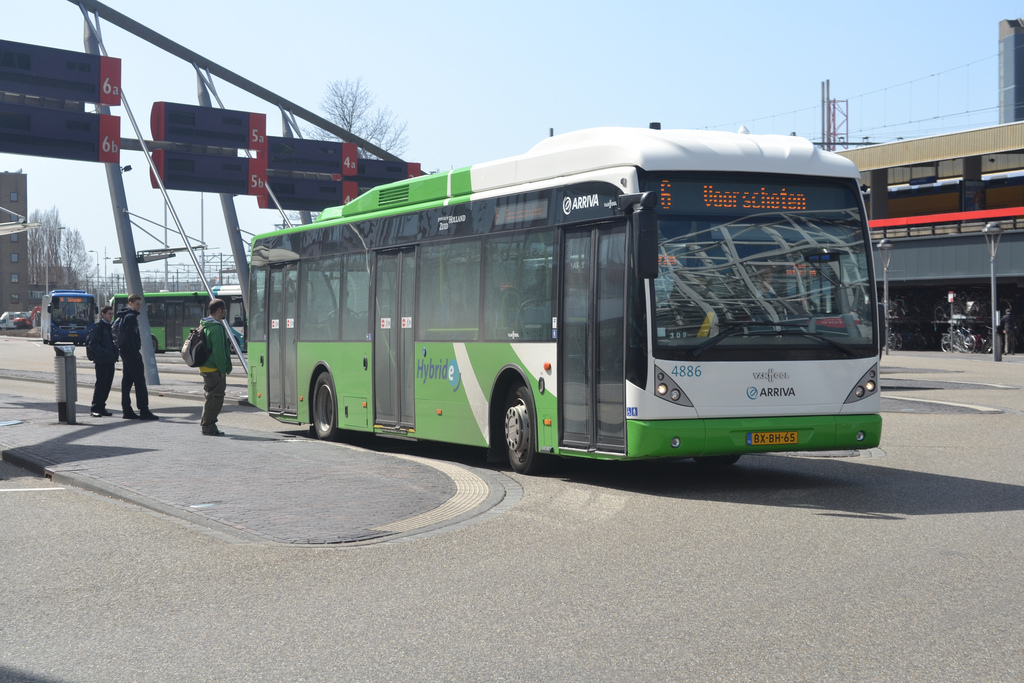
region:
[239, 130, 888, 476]
bus with green and white paint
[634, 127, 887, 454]
large front windows of bus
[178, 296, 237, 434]
man wearing green jacket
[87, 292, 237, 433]
people waiting on a bus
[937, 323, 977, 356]
bicycle in bicycle rack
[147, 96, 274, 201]
pair of black and red signs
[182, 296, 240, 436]
man wearing black backpack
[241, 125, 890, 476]
orange lettering on bus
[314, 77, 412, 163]
tall tree without leaves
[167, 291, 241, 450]
a person is standing up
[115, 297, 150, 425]
a person is standing up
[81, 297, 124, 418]
a person is standing up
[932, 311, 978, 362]
a two wheeled bicycle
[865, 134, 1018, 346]
a building in a city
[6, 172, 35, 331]
a building in a city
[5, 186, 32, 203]
a window on a building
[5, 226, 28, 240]
a window on a building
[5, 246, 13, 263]
a window on a building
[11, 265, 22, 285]
a window on a building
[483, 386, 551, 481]
tired on bus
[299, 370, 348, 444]
back tire on bus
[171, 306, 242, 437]
man standing next to bus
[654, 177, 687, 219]
the number 6 on the green bus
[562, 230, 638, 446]
the door on the bus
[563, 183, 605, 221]
letters above the door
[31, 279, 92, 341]
a blue bus is far away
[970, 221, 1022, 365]
a street light on the road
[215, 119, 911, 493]
white and green bus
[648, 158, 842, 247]
sign on the bus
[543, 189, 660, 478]
doors on the bus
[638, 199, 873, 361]
front window on the bus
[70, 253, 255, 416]
a group of people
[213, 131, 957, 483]
green and white bus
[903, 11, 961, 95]
white clouds in blue sky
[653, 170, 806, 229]
orange sign on bus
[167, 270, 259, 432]
man waiting for bus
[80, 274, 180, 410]
man waiting for bus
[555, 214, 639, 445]
closed bus door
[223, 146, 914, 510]
green and white city bus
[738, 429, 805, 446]
yellow license plate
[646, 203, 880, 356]
large window on front of bus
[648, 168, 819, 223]
orange letters on front of bus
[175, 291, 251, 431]
man wearing green jacket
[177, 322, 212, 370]
black backpack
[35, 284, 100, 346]
blue city bus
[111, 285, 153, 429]
man wearing black jacket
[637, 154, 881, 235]
digital display on bus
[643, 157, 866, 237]
digital display on bus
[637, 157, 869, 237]
digital display on bus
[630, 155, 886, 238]
digital display on bus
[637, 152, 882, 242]
digital display on bus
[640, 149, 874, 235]
digital display on bus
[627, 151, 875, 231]
digital display on bus